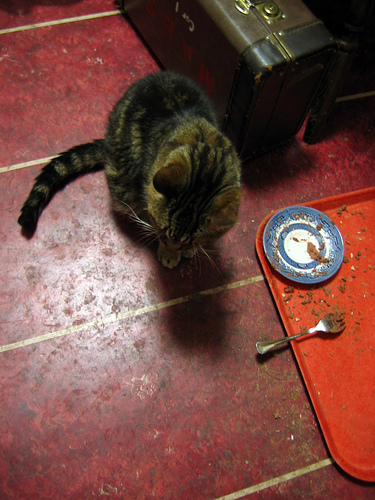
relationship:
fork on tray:
[269, 301, 364, 374] [249, 195, 369, 390]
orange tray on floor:
[254, 186, 372, 483] [5, 275, 250, 495]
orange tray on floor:
[254, 186, 372, 483] [5, 4, 100, 129]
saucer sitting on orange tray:
[262, 205, 342, 285] [254, 186, 372, 483]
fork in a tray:
[254, 307, 350, 362] [238, 161, 368, 433]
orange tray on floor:
[254, 186, 372, 483] [1, 0, 373, 496]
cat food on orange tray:
[284, 209, 363, 327] [254, 186, 372, 483]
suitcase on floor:
[194, 2, 362, 149] [78, 315, 281, 482]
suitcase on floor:
[111, 0, 340, 161] [1, 0, 373, 330]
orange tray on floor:
[254, 186, 372, 483] [78, 315, 281, 482]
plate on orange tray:
[261, 203, 347, 287] [254, 186, 372, 483]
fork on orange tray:
[254, 307, 350, 362] [254, 186, 372, 483]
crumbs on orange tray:
[320, 265, 355, 322] [254, 186, 372, 483]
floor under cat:
[1, 0, 373, 496] [13, 68, 243, 269]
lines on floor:
[3, 7, 276, 496] [33, 301, 213, 460]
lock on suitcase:
[234, 0, 283, 23] [111, 0, 340, 161]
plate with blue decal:
[261, 203, 347, 287] [275, 223, 341, 283]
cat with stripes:
[13, 68, 243, 269] [135, 105, 228, 207]